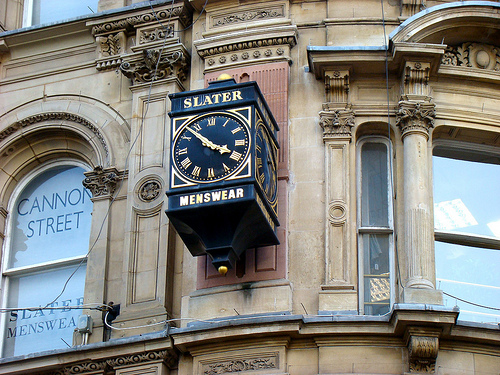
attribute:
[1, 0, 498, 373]
pillar — ornate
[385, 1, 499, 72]
arch — decorative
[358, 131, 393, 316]
window — narrow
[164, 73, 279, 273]
blue clock — roman letter clock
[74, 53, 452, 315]
building — slater menswear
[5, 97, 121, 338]
arch — decorative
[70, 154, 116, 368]
pillar — ornate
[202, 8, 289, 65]
decorations — ornate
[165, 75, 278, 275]
clock — roman letter clock, fixed, clock face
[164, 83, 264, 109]
brandname — written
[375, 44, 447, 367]
design — pillar design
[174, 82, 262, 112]
slater — written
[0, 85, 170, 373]
street — cannon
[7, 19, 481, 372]
building — brown, coated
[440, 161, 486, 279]
lights — fluorescent 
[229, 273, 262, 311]
spot — dark